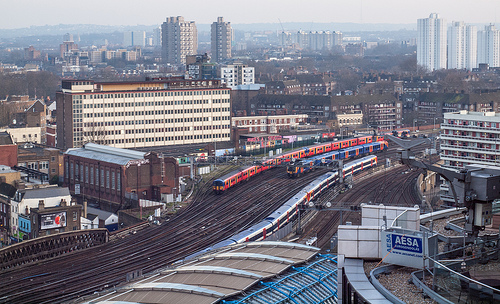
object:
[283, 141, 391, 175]
train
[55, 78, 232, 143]
large building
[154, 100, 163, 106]
windows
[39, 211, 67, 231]
adverstisment sign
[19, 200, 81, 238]
building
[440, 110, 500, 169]
large building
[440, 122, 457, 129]
balcony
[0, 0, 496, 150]
city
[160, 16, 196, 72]
high rise building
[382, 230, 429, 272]
aesa sign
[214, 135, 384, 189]
red train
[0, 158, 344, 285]
railroad tracks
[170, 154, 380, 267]
silver train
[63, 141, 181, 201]
building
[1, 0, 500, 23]
sky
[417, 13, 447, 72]
building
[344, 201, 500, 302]
building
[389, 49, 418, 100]
building